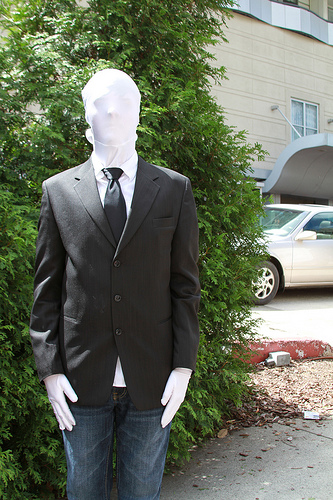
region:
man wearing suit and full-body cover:
[31, 62, 200, 499]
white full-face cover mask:
[79, 66, 142, 162]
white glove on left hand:
[155, 365, 194, 432]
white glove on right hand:
[41, 372, 79, 434]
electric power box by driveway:
[265, 348, 292, 368]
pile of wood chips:
[230, 365, 331, 410]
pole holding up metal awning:
[270, 102, 301, 140]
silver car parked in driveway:
[252, 194, 331, 302]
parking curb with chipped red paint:
[229, 336, 329, 364]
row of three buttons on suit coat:
[110, 253, 124, 343]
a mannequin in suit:
[33, 42, 214, 484]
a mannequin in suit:
[29, 63, 175, 312]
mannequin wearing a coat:
[26, 47, 196, 496]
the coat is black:
[29, 172, 204, 423]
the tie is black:
[99, 157, 151, 238]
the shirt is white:
[88, 156, 130, 208]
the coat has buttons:
[78, 234, 141, 366]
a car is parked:
[235, 186, 323, 359]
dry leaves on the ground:
[243, 360, 327, 438]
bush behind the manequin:
[17, 41, 251, 482]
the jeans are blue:
[59, 359, 196, 463]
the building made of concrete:
[215, 13, 322, 190]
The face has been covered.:
[77, 61, 145, 161]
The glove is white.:
[41, 363, 85, 434]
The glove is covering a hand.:
[154, 361, 196, 435]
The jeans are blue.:
[62, 378, 181, 498]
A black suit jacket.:
[30, 154, 203, 394]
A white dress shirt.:
[86, 151, 144, 239]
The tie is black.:
[95, 162, 135, 248]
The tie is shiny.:
[102, 163, 131, 249]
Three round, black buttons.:
[107, 250, 127, 350]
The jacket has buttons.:
[45, 188, 182, 409]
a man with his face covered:
[64, 78, 156, 170]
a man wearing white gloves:
[149, 357, 194, 428]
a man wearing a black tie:
[103, 56, 159, 233]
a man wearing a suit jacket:
[29, 87, 207, 414]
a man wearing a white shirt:
[56, 142, 157, 244]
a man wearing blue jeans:
[71, 301, 190, 480]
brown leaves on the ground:
[191, 370, 329, 472]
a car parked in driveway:
[222, 191, 326, 309]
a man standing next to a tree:
[36, 48, 198, 366]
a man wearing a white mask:
[56, 69, 171, 224]